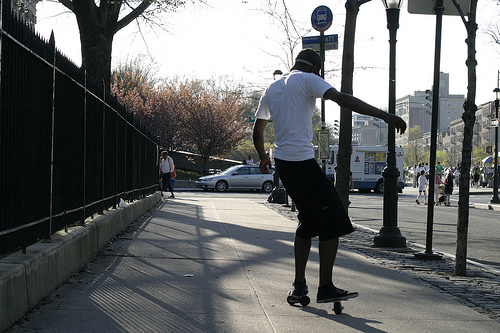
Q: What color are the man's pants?
A: Black.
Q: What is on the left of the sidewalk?
A: A fence.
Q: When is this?
A: Daytime.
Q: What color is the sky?
A: White.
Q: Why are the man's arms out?
A: For balance.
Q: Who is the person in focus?
A: The man.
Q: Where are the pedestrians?
A: On the street in the background.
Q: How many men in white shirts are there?
A: One.